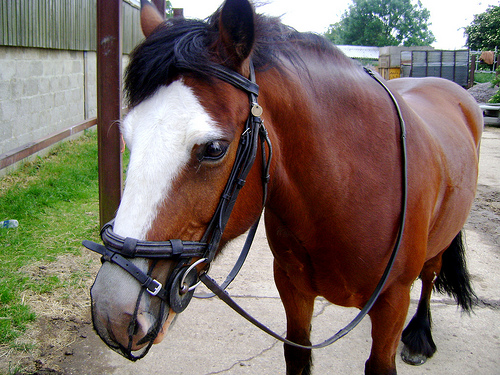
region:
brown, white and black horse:
[90, 1, 479, 373]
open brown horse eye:
[197, 133, 234, 165]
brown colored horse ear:
[209, 2, 256, 60]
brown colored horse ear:
[136, 0, 164, 38]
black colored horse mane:
[123, 12, 344, 106]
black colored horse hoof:
[443, 238, 478, 315]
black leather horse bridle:
[77, 37, 414, 364]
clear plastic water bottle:
[1, 219, 20, 226]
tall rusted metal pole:
[93, 4, 123, 234]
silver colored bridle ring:
[180, 257, 213, 293]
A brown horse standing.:
[86, 18, 472, 374]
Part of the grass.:
[28, 175, 81, 218]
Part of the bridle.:
[98, 226, 228, 306]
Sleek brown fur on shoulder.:
[296, 93, 374, 195]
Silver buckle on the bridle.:
[146, 278, 161, 295]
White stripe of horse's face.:
[116, 85, 196, 241]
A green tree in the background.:
[328, 1, 433, 45]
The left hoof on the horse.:
[400, 335, 429, 366]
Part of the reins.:
[233, 297, 344, 355]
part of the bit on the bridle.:
[178, 261, 210, 291]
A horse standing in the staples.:
[129, 78, 476, 358]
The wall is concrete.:
[11, 48, 87, 123]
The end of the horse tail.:
[432, 216, 469, 304]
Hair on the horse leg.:
[395, 313, 436, 370]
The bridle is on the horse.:
[200, 104, 269, 337]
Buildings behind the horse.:
[343, 48, 477, 86]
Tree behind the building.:
[345, 13, 449, 57]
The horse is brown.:
[268, 15, 480, 278]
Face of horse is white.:
[121, 98, 188, 214]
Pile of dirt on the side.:
[471, 80, 498, 114]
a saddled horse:
[89, 1, 481, 373]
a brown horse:
[86, 0, 478, 372]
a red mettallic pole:
[100, 0, 120, 217]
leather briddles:
[101, 236, 181, 291]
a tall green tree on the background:
[351, 9, 423, 40]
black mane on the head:
[125, 23, 192, 95]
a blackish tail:
[448, 242, 478, 312]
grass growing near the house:
[26, 165, 90, 208]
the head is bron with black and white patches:
[88, 6, 259, 353]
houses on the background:
[346, 43, 418, 61]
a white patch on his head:
[107, 85, 221, 266]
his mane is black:
[121, 2, 298, 110]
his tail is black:
[438, 222, 484, 322]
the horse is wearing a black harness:
[96, 17, 418, 360]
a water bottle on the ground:
[0, 220, 27, 230]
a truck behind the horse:
[385, 44, 473, 91]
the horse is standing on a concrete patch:
[50, 120, 491, 370]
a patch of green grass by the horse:
[3, 126, 104, 260]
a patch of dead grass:
[10, 246, 107, 373]